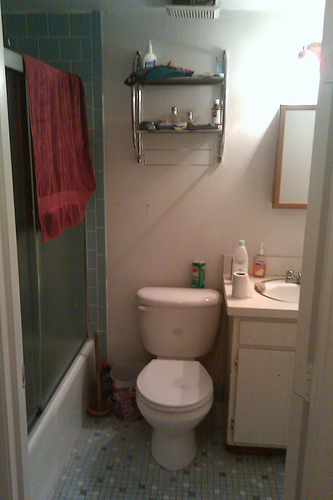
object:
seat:
[135, 356, 213, 414]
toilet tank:
[133, 284, 224, 360]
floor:
[49, 400, 290, 499]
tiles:
[106, 462, 114, 471]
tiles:
[218, 470, 227, 479]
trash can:
[109, 360, 145, 421]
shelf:
[124, 45, 230, 88]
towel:
[20, 52, 98, 245]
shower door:
[0, 47, 99, 499]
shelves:
[130, 82, 227, 165]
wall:
[106, 1, 324, 392]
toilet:
[134, 285, 223, 471]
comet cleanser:
[189, 260, 206, 288]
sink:
[253, 276, 301, 303]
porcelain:
[135, 306, 221, 358]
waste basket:
[112, 384, 141, 424]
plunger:
[85, 329, 112, 420]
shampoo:
[231, 238, 248, 280]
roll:
[230, 271, 250, 300]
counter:
[222, 271, 301, 320]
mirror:
[272, 103, 316, 212]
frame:
[272, 104, 316, 206]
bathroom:
[0, 1, 333, 500]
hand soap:
[253, 242, 267, 279]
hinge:
[230, 414, 236, 432]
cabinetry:
[226, 316, 296, 452]